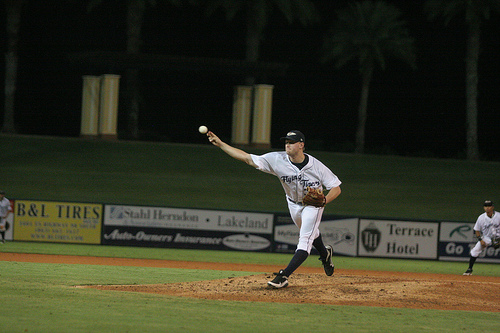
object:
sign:
[102, 205, 275, 252]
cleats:
[265, 243, 335, 290]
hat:
[272, 125, 314, 147]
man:
[169, 95, 364, 287]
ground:
[418, 135, 452, 166]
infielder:
[459, 199, 499, 278]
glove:
[305, 187, 327, 207]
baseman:
[197, 116, 359, 290]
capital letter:
[387, 241, 396, 253]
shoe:
[266, 269, 288, 289]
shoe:
[321, 243, 336, 277]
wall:
[3, 197, 497, 262]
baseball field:
[3, 131, 494, 329]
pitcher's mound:
[137, 265, 499, 312]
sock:
[276, 248, 308, 276]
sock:
[310, 235, 326, 257]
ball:
[194, 122, 209, 135]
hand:
[207, 130, 221, 146]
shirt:
[247, 151, 347, 201]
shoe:
[462, 270, 473, 275]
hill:
[14, 127, 480, 235]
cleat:
[262, 272, 293, 290]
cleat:
[319, 245, 335, 275]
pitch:
[193, 123, 261, 166]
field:
[0, 239, 497, 330]